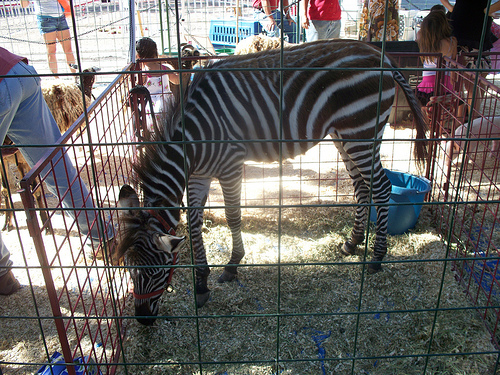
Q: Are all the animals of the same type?
A: No, there are both goats and zebras.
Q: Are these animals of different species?
A: Yes, they are goats and zebras.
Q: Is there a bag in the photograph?
A: No, there are no bags.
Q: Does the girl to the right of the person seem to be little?
A: Yes, the girl is little.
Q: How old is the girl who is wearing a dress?
A: The girl is little.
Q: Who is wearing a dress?
A: The girl is wearing a dress.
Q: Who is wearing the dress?
A: The girl is wearing a dress.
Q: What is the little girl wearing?
A: The girl is wearing a dress.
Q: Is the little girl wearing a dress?
A: Yes, the girl is wearing a dress.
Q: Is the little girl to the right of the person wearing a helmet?
A: No, the girl is wearing a dress.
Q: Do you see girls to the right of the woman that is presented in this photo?
A: Yes, there is a girl to the right of the woman.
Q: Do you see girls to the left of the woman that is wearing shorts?
A: No, the girl is to the right of the woman.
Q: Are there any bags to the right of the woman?
A: No, there is a girl to the right of the woman.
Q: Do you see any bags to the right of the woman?
A: No, there is a girl to the right of the woman.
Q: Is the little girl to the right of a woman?
A: Yes, the girl is to the right of a woman.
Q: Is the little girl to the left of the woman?
A: No, the girl is to the right of the woman.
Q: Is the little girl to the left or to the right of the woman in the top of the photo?
A: The girl is to the right of the woman.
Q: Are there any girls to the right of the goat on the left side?
A: Yes, there is a girl to the right of the goat.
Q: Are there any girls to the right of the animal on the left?
A: Yes, there is a girl to the right of the goat.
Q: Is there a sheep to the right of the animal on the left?
A: No, there is a girl to the right of the goat.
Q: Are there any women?
A: Yes, there is a woman.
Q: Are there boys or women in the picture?
A: Yes, there is a woman.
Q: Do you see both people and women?
A: Yes, there are both a woman and a person.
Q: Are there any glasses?
A: No, there are no glasses.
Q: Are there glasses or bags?
A: No, there are no glasses or bags.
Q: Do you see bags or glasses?
A: No, there are no glasses or bags.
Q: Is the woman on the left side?
A: Yes, the woman is on the left of the image.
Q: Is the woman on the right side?
A: No, the woman is on the left of the image.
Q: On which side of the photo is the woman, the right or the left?
A: The woman is on the left of the image.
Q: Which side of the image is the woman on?
A: The woman is on the left of the image.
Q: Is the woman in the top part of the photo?
A: Yes, the woman is in the top of the image.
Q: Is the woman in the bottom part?
A: No, the woman is in the top of the image.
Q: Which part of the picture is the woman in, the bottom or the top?
A: The woman is in the top of the image.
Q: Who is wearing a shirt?
A: The woman is wearing a shirt.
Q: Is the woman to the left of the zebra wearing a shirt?
A: Yes, the woman is wearing a shirt.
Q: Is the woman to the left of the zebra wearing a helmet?
A: No, the woman is wearing a shirt.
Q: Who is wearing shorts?
A: The woman is wearing shorts.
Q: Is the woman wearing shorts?
A: Yes, the woman is wearing shorts.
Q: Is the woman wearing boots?
A: No, the woman is wearing shorts.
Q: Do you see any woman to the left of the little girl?
A: Yes, there is a woman to the left of the girl.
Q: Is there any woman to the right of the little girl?
A: No, the woman is to the left of the girl.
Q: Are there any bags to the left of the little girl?
A: No, there is a woman to the left of the girl.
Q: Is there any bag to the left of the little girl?
A: No, there is a woman to the left of the girl.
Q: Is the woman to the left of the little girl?
A: Yes, the woman is to the left of the girl.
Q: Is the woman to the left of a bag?
A: No, the woman is to the left of the girl.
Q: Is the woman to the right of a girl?
A: No, the woman is to the left of a girl.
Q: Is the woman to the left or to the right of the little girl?
A: The woman is to the left of the girl.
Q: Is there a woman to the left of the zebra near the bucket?
A: Yes, there is a woman to the left of the zebra.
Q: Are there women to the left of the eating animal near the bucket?
A: Yes, there is a woman to the left of the zebra.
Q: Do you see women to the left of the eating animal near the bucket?
A: Yes, there is a woman to the left of the zebra.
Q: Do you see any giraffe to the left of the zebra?
A: No, there is a woman to the left of the zebra.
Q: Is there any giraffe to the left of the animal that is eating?
A: No, there is a woman to the left of the zebra.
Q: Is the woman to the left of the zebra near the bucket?
A: Yes, the woman is to the left of the zebra.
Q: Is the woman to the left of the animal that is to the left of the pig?
A: Yes, the woman is to the left of the zebra.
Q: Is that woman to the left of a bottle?
A: No, the woman is to the left of the zebra.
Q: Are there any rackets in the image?
A: No, there are no rackets.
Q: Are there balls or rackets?
A: No, there are no rackets or balls.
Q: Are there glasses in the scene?
A: No, there are no glasses.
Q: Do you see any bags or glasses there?
A: No, there are no glasses or bags.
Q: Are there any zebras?
A: Yes, there is a zebra.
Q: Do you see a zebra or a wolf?
A: Yes, there is a zebra.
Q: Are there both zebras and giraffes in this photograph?
A: No, there is a zebra but no giraffes.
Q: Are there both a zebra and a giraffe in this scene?
A: No, there is a zebra but no giraffes.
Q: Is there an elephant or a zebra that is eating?
A: Yes, the zebra is eating.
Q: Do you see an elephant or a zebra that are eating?
A: Yes, the zebra is eating.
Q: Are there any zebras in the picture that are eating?
A: Yes, there is a zebra that is eating.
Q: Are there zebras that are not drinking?
A: Yes, there is a zebra that is eating.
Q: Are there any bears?
A: No, there are no bears.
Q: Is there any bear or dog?
A: No, there are no bears or dogs.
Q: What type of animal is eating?
A: The animal is a zebra.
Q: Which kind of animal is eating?
A: The animal is a zebra.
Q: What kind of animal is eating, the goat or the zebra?
A: The zebra is eating.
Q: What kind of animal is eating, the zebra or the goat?
A: The zebra is eating.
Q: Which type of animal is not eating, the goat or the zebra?
A: The goat is not eating.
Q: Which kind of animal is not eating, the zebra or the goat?
A: The goat is not eating.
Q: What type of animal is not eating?
A: The animal is a goat.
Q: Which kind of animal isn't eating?
A: The animal is a goat.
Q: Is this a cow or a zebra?
A: This is a zebra.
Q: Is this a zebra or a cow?
A: This is a zebra.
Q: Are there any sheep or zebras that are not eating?
A: No, there is a zebra but it is eating.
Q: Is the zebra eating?
A: Yes, the zebra is eating.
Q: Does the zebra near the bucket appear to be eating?
A: Yes, the zebra is eating.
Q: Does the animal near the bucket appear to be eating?
A: Yes, the zebra is eating.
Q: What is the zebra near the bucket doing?
A: The zebra is eating.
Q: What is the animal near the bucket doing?
A: The zebra is eating.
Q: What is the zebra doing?
A: The zebra is eating.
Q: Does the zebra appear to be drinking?
A: No, the zebra is eating.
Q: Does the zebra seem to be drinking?
A: No, the zebra is eating.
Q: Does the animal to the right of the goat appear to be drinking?
A: No, the zebra is eating.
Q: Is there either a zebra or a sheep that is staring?
A: No, there is a zebra but it is eating.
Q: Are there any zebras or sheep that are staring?
A: No, there is a zebra but it is eating.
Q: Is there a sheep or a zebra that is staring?
A: No, there is a zebra but it is eating.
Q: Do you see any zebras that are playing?
A: No, there is a zebra but it is eating.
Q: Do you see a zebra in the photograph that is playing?
A: No, there is a zebra but it is eating.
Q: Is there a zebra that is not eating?
A: No, there is a zebra but it is eating.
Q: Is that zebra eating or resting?
A: The zebra is eating.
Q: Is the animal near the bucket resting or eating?
A: The zebra is eating.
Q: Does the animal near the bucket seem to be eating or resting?
A: The zebra is eating.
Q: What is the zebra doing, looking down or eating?
A: The zebra is eating.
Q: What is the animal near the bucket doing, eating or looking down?
A: The zebra is eating.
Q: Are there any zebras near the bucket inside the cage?
A: Yes, there is a zebra near the bucket.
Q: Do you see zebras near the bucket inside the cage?
A: Yes, there is a zebra near the bucket.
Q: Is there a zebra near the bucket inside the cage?
A: Yes, there is a zebra near the bucket.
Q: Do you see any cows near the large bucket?
A: No, there is a zebra near the bucket.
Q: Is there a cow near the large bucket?
A: No, there is a zebra near the bucket.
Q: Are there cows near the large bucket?
A: No, there is a zebra near the bucket.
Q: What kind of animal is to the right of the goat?
A: The animal is a zebra.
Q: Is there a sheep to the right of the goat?
A: No, there is a zebra to the right of the goat.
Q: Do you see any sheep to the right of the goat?
A: No, there is a zebra to the right of the goat.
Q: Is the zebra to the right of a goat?
A: Yes, the zebra is to the right of a goat.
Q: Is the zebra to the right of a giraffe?
A: No, the zebra is to the right of a goat.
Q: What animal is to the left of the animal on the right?
A: The animal is a zebra.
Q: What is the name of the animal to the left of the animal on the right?
A: The animal is a zebra.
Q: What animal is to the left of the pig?
A: The animal is a zebra.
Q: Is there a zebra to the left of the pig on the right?
A: Yes, there is a zebra to the left of the pig.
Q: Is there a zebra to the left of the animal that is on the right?
A: Yes, there is a zebra to the left of the pig.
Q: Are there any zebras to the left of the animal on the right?
A: Yes, there is a zebra to the left of the pig.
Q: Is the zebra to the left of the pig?
A: Yes, the zebra is to the left of the pig.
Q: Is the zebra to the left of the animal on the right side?
A: Yes, the zebra is to the left of the pig.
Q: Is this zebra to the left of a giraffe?
A: No, the zebra is to the left of the pig.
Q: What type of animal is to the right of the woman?
A: The animal is a zebra.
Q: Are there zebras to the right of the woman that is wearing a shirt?
A: Yes, there is a zebra to the right of the woman.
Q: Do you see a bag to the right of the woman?
A: No, there is a zebra to the right of the woman.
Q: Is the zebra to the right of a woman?
A: Yes, the zebra is to the right of a woman.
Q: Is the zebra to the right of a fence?
A: No, the zebra is to the right of a woman.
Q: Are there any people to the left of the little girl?
A: Yes, there is a person to the left of the girl.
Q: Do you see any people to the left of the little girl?
A: Yes, there is a person to the left of the girl.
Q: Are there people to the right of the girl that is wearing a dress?
A: No, the person is to the left of the girl.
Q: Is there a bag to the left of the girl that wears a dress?
A: No, there is a person to the left of the girl.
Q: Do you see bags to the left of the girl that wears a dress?
A: No, there is a person to the left of the girl.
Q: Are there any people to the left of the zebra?
A: Yes, there is a person to the left of the zebra.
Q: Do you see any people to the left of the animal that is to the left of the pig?
A: Yes, there is a person to the left of the zebra.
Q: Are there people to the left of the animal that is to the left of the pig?
A: Yes, there is a person to the left of the zebra.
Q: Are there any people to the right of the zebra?
A: No, the person is to the left of the zebra.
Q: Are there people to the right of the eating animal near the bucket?
A: No, the person is to the left of the zebra.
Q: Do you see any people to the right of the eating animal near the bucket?
A: No, the person is to the left of the zebra.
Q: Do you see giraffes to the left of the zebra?
A: No, there is a person to the left of the zebra.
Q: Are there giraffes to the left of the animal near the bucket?
A: No, there is a person to the left of the zebra.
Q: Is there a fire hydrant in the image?
A: No, there are no fire hydrants.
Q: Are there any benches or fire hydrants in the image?
A: No, there are no fire hydrants or benches.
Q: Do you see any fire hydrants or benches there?
A: No, there are no fire hydrants or benches.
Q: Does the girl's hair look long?
A: Yes, the hair is long.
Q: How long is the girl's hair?
A: The hair is long.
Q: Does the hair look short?
A: No, the hair is long.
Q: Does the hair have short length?
A: No, the hair is long.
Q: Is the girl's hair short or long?
A: The hair is long.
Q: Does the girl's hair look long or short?
A: The hair is long.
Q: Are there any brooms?
A: No, there are no brooms.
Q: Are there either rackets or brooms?
A: No, there are no brooms or rackets.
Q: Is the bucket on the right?
A: Yes, the bucket is on the right of the image.